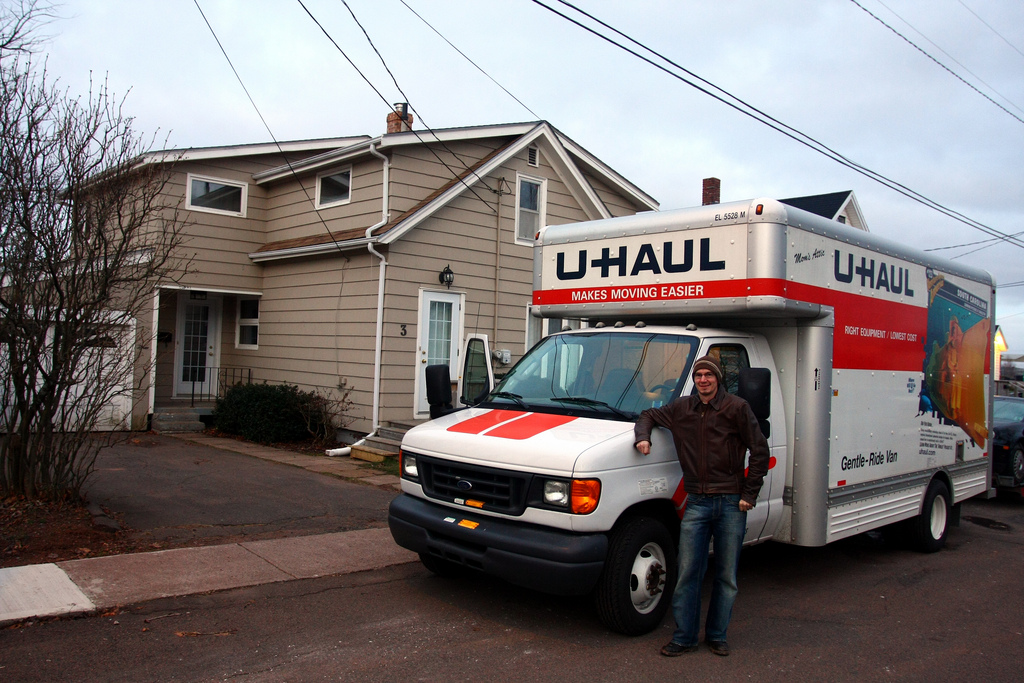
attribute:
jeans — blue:
[662, 487, 752, 655]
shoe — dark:
[704, 625, 737, 651]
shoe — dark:
[656, 629, 694, 655]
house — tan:
[2, 107, 658, 441]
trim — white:
[2, 107, 658, 441]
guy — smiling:
[636, 348, 766, 649]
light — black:
[444, 261, 458, 287]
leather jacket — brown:
[636, 392, 769, 498]